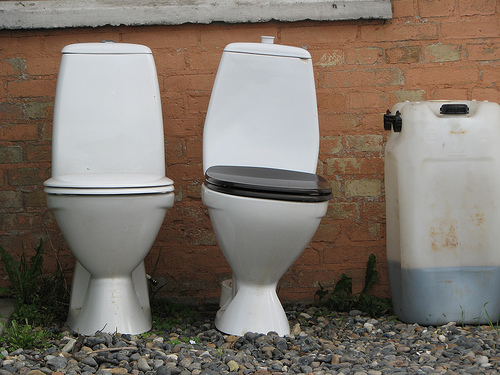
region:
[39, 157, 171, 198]
the lid is white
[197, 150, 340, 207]
the lid is black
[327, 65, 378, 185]
the wall is brick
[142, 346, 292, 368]
the gravel is gray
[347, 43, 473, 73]
the wall is red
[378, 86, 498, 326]
the container is beside the toilet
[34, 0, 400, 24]
the ledge is gray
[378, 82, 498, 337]
the container is a quarter full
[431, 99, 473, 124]
the cap is black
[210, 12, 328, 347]
the toilet is tilted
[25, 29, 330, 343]
toilets by the wall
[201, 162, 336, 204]
a black toilet seat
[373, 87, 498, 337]
a jug of liquid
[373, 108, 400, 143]
the knozzle for the jug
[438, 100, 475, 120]
the cap for the jug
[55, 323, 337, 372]
rocks on the ground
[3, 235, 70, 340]
weeds by the toilet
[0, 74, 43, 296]
the wall is dirty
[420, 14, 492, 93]
the brick wall is peeling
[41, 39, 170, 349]
an all white toilet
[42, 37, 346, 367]
two toilets sitting outside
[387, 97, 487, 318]
a large plastic container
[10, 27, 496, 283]
a weathered brick wall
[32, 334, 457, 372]
a patch of gravel on the ground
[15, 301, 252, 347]
a patch of plants by the wall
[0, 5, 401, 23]
the edge of a window sill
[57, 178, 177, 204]
a white toilet seat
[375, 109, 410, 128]
a black plastic stopper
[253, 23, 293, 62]
a flushing mechanism on a toilet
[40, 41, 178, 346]
a white porcelain toilet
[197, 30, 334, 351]
a white porcelain toilet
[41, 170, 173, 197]
a white plastic toilet lid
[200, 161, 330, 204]
a black plastic toilet lid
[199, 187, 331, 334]
a white toilet bowl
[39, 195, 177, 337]
a white toilet bowl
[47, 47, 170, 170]
a white toilet tank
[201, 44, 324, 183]
a white toilet tank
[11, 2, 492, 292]
an orange brick wall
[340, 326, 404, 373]
tiny rocks on the ground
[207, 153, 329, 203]
a black toilet seat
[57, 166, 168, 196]
a white toilet lid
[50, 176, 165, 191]
a white toilet seat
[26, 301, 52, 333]
grass by the toilet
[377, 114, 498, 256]
a white container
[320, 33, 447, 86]
a brick wall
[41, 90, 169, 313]
a white toilet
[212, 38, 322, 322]
a black and white toilet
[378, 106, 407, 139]
black handle on the container